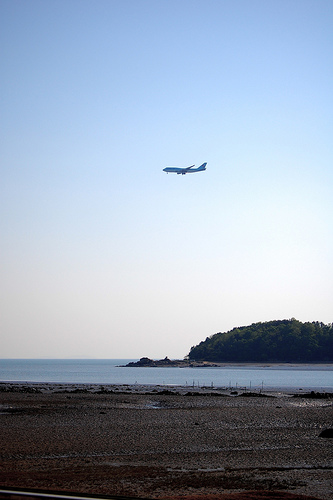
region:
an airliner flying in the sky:
[161, 158, 207, 175]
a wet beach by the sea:
[4, 379, 330, 495]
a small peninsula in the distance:
[118, 320, 330, 369]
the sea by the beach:
[2, 357, 329, 392]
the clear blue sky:
[4, 3, 329, 358]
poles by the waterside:
[125, 379, 268, 390]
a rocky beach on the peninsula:
[118, 352, 331, 371]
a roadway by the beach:
[2, 484, 119, 498]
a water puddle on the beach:
[142, 400, 166, 409]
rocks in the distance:
[117, 355, 219, 366]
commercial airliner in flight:
[135, 151, 232, 193]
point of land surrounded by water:
[103, 341, 213, 374]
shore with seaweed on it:
[137, 378, 310, 409]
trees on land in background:
[180, 314, 317, 368]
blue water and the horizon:
[11, 340, 112, 378]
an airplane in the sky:
[155, 145, 239, 192]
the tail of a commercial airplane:
[196, 157, 208, 174]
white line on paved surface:
[3, 479, 107, 498]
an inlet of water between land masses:
[84, 298, 329, 424]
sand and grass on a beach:
[32, 367, 167, 452]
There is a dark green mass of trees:
[277, 320, 311, 364]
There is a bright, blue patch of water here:
[75, 360, 84, 370]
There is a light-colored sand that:
[176, 428, 188, 449]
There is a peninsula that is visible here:
[141, 349, 178, 364]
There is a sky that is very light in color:
[82, 294, 95, 325]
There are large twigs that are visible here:
[252, 378, 263, 389]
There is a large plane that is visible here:
[165, 144, 213, 198]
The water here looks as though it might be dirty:
[11, 358, 18, 375]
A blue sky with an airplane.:
[0, 1, 312, 315]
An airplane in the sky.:
[158, 158, 209, 179]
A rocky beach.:
[2, 377, 329, 496]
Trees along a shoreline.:
[181, 316, 328, 366]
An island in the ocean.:
[116, 353, 229, 369]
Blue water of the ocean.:
[3, 356, 328, 387]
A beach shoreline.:
[213, 361, 330, 372]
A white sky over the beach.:
[3, 305, 189, 349]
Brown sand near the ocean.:
[1, 381, 328, 498]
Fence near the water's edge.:
[175, 377, 285, 394]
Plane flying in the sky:
[157, 159, 212, 179]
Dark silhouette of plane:
[160, 160, 210, 183]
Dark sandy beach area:
[3, 378, 330, 498]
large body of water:
[3, 360, 332, 394]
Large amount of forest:
[187, 317, 331, 357]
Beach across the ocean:
[127, 355, 330, 370]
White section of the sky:
[1, 190, 329, 358]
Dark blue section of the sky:
[0, 0, 330, 104]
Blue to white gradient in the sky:
[4, 101, 332, 224]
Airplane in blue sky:
[163, 159, 209, 180]